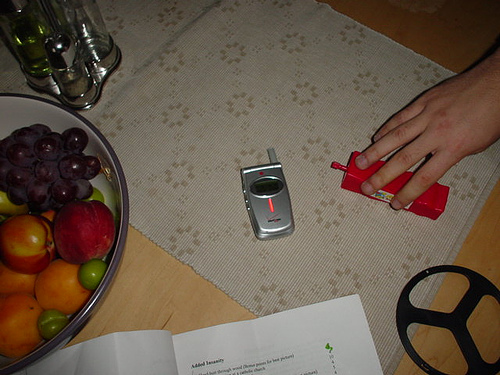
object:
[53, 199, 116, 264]
peach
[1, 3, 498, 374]
table runner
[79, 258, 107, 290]
lime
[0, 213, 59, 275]
apple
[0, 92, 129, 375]
bowl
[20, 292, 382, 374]
book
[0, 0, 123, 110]
shaker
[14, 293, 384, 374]
paper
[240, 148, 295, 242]
cell phone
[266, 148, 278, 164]
antenna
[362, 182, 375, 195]
nail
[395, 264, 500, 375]
sterring wheel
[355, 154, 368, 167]
nail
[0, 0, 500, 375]
placemat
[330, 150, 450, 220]
case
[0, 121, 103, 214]
grapes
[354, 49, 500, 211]
hand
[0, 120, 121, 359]
fruit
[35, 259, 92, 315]
orange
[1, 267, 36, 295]
orange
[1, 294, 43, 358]
orange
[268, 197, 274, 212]
red light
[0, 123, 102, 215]
cluster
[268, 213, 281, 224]
verizon printed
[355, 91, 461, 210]
fingers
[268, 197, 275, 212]
light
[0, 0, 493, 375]
table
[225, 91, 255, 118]
design